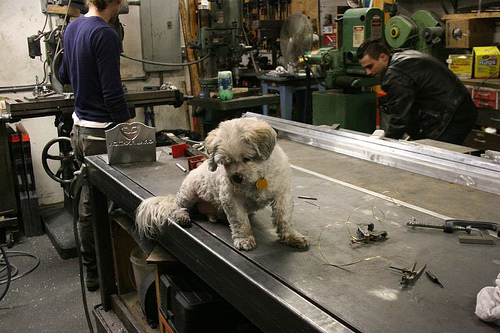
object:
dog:
[134, 117, 312, 252]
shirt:
[58, 16, 132, 124]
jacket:
[378, 49, 469, 140]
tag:
[256, 177, 269, 191]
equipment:
[303, 6, 445, 135]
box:
[472, 46, 500, 79]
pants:
[70, 123, 121, 287]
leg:
[277, 83, 293, 120]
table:
[81, 126, 500, 332]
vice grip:
[406, 218, 500, 244]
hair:
[356, 39, 391, 61]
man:
[356, 39, 479, 145]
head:
[205, 117, 277, 186]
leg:
[271, 174, 311, 248]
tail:
[132, 194, 180, 240]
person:
[55, 0, 132, 292]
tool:
[388, 259, 428, 286]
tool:
[164, 130, 210, 172]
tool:
[425, 270, 444, 288]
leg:
[219, 175, 255, 251]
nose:
[232, 172, 244, 183]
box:
[446, 53, 473, 80]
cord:
[0, 246, 40, 301]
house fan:
[280, 12, 314, 123]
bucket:
[129, 247, 157, 313]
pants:
[437, 92, 479, 145]